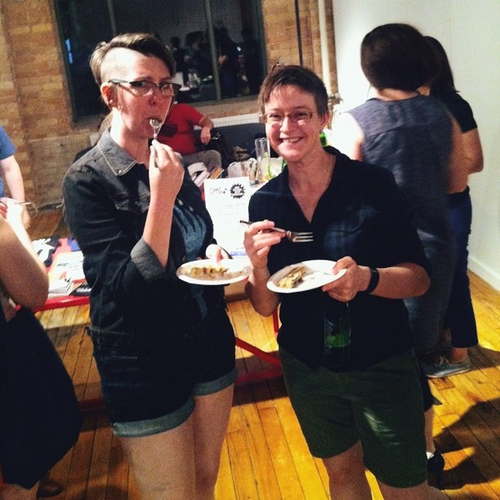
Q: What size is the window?
A: Big.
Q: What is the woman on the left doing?
A: Eating.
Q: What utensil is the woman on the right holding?
A: A fork.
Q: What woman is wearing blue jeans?
A: The one on the left.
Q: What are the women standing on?
A: A wooden floor.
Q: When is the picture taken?
A: Nighttime.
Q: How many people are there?
A: 7.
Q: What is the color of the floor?
A: Brown.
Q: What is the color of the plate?
A: White.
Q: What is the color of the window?
A: Black.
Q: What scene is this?
A: Dinner.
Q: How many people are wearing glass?
A: 2.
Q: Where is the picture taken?
A: In an urban apartment.